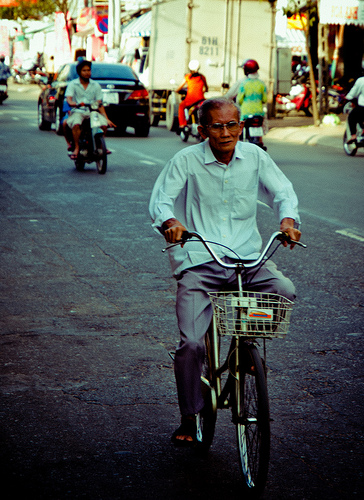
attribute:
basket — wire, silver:
[205, 284, 312, 335]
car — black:
[39, 51, 173, 148]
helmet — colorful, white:
[239, 53, 269, 78]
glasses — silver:
[198, 117, 245, 133]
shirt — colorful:
[148, 144, 305, 268]